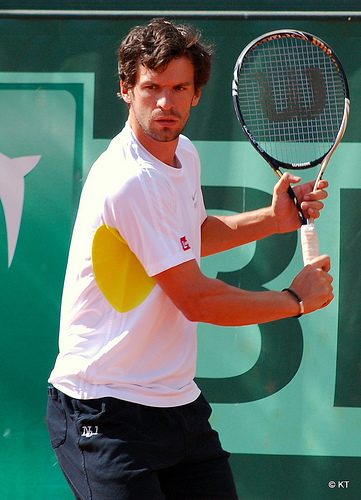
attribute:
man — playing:
[39, 11, 339, 499]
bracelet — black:
[277, 285, 307, 324]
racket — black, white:
[229, 23, 359, 285]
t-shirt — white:
[41, 123, 219, 419]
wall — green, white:
[5, 3, 360, 495]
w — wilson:
[255, 57, 336, 126]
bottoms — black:
[39, 383, 241, 498]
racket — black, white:
[210, 44, 343, 276]